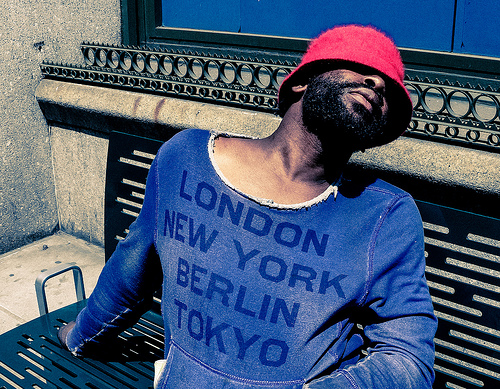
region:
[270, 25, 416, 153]
red hat on the man's head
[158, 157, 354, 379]
city names on the man's shirt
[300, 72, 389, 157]
black beard and mustache on the man's face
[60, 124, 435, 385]
a blue long sleaved shirt on the man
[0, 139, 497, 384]
the man is sitting on a black bench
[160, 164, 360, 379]
blue cities in capital letters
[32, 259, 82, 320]
metal handle on the bench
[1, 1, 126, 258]
concrete wall in the background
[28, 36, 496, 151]
metal decoration on a wall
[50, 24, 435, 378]
a man sitting on a bench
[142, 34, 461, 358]
A man in a red hut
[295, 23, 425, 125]
A red hut on the man's head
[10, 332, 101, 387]
A black metalic street chair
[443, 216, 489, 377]
A black metalic street chair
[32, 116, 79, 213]
A cement street wall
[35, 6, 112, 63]
A cement street wall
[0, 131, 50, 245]
A cement street wall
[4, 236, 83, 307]
A cement street floor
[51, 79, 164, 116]
A cement street wall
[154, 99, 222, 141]
A cement street wall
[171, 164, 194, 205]
The lettering is blue.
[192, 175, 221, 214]
The lettering is blue.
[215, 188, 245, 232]
The lettering is blue.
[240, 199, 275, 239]
The lettering is blue.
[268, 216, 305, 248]
The lettering is blue.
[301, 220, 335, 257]
The lettering is blue.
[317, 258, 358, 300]
The lettering is blue.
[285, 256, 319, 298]
The lettering is blue.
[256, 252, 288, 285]
The lettering is blue.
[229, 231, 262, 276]
The lettering is blue.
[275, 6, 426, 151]
big red hat on man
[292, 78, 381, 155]
very bushy bearded man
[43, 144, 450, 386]
long sleeve shirt with different cities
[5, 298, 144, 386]
big bench to sit on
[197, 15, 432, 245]
man enjoying the sun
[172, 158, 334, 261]
shirt that says london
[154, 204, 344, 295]
shirt that says new york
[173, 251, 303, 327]
shirt that says berlin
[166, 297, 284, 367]
shirt that says tokyo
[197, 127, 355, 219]
large neck on sweat shirt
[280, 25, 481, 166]
face of the person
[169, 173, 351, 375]
a text written in shirt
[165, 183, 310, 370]
text on the shirt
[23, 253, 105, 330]
a small handle of bench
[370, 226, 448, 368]
hand of the person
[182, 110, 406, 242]
round shirt of the person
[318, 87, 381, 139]
beard of the person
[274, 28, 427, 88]
red cap wearing by person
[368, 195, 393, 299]
a small line in shirt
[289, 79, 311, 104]
ear of the person